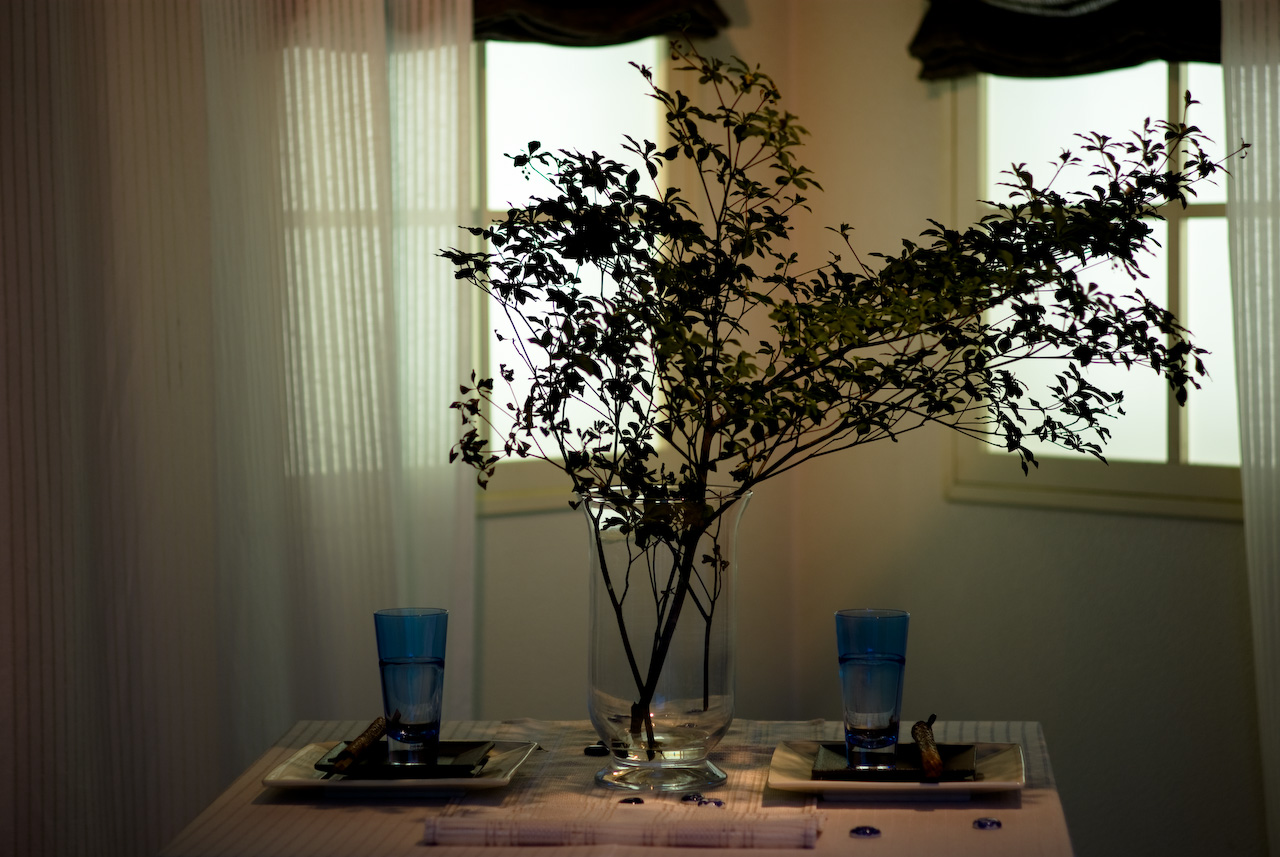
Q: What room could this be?
A: It is a dining room.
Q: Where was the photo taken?
A: It was taken at the dining room.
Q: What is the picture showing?
A: It is showing a dining room.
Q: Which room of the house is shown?
A: It is a dining room.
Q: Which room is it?
A: It is a dining room.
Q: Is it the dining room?
A: Yes, it is the dining room.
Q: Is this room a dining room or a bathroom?
A: It is a dining room.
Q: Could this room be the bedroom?
A: No, it is the dining room.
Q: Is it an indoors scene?
A: Yes, it is indoors.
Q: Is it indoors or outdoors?
A: It is indoors.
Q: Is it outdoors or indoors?
A: It is indoors.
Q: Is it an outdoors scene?
A: No, it is indoors.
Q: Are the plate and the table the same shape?
A: Yes, both the plate and the table are square.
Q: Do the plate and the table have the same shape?
A: Yes, both the plate and the table are square.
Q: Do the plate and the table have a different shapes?
A: No, both the plate and the table are square.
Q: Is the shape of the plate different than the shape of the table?
A: No, both the plate and the table are square.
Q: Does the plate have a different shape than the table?
A: No, both the plate and the table are square.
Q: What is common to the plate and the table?
A: The shape, both the plate and the table are square.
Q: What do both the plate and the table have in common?
A: The shape, both the plate and the table are square.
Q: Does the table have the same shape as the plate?
A: Yes, both the table and the plate are square.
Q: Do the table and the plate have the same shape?
A: Yes, both the table and the plate are square.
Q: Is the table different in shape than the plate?
A: No, both the table and the plate are square.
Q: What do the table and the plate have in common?
A: The shape, both the table and the plate are square.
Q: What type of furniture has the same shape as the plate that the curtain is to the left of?
A: The table is the same shape as the plate.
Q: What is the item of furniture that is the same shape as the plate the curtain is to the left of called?
A: The piece of furniture is a table.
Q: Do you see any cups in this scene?
A: Yes, there is a cup.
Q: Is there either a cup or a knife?
A: Yes, there is a cup.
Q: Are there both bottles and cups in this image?
A: No, there is a cup but no bottles.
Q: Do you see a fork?
A: No, there are no forks.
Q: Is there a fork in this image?
A: No, there are no forks.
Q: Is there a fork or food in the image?
A: No, there are no forks or food.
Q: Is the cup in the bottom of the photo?
A: Yes, the cup is in the bottom of the image.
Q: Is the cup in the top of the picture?
A: No, the cup is in the bottom of the image.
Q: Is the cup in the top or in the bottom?
A: The cup is in the bottom of the image.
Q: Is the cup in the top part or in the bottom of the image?
A: The cup is in the bottom of the image.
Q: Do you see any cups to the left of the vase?
A: Yes, there is a cup to the left of the vase.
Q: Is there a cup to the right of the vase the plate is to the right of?
A: No, the cup is to the left of the vase.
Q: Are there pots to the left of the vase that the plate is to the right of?
A: No, there is a cup to the left of the vase.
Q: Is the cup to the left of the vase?
A: Yes, the cup is to the left of the vase.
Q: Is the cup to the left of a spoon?
A: No, the cup is to the left of the vase.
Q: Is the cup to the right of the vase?
A: No, the cup is to the left of the vase.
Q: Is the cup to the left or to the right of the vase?
A: The cup is to the left of the vase.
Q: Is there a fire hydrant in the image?
A: No, there are no fire hydrants.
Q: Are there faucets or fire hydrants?
A: No, there are no fire hydrants or faucets.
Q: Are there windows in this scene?
A: Yes, there is a window.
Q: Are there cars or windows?
A: Yes, there is a window.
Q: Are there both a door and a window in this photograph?
A: No, there is a window but no doors.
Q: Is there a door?
A: No, there are no doors.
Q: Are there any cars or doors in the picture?
A: No, there are no doors or cars.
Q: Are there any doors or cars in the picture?
A: No, there are no doors or cars.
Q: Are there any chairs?
A: No, there are no chairs.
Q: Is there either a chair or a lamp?
A: No, there are no chairs or lamps.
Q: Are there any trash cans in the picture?
A: No, there are no trash cans.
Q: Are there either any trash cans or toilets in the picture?
A: No, there are no trash cans or toilets.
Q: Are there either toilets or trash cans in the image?
A: No, there are no trash cans or toilets.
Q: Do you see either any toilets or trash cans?
A: No, there are no trash cans or toilets.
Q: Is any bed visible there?
A: No, there are no beds.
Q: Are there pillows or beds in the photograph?
A: No, there are no beds or pillows.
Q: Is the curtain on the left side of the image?
A: Yes, the curtain is on the left of the image.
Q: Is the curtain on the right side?
A: No, the curtain is on the left of the image.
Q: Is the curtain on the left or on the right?
A: The curtain is on the left of the image.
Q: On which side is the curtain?
A: The curtain is on the left of the image.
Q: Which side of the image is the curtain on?
A: The curtain is on the left of the image.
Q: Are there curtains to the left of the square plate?
A: Yes, there is a curtain to the left of the plate.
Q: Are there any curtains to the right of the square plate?
A: No, the curtain is to the left of the plate.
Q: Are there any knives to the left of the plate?
A: No, there is a curtain to the left of the plate.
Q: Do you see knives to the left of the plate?
A: No, there is a curtain to the left of the plate.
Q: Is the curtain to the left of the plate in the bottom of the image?
A: Yes, the curtain is to the left of the plate.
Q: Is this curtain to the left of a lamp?
A: No, the curtain is to the left of the plate.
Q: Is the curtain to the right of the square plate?
A: No, the curtain is to the left of the plate.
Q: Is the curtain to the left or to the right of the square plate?
A: The curtain is to the left of the plate.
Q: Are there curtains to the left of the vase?
A: Yes, there is a curtain to the left of the vase.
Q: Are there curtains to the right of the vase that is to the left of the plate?
A: No, the curtain is to the left of the vase.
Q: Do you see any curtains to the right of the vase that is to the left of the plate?
A: No, the curtain is to the left of the vase.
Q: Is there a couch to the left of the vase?
A: No, there is a curtain to the left of the vase.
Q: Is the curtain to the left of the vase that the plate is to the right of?
A: Yes, the curtain is to the left of the vase.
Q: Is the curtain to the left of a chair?
A: No, the curtain is to the left of the vase.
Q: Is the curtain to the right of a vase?
A: No, the curtain is to the left of a vase.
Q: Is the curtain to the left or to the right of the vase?
A: The curtain is to the left of the vase.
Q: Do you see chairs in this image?
A: No, there are no chairs.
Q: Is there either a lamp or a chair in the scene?
A: No, there are no chairs or lamps.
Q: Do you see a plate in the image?
A: Yes, there is a plate.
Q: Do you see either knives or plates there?
A: Yes, there is a plate.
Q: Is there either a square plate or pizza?
A: Yes, there is a square plate.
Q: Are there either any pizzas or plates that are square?
A: Yes, the plate is square.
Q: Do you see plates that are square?
A: Yes, there is a square plate.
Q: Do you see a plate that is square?
A: Yes, there is a plate that is square.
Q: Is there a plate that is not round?
A: Yes, there is a square plate.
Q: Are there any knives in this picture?
A: No, there are no knives.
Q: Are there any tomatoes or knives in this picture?
A: No, there are no knives or tomatoes.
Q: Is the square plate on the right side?
A: Yes, the plate is on the right of the image.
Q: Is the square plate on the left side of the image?
A: No, the plate is on the right of the image.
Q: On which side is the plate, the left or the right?
A: The plate is on the right of the image.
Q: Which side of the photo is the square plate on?
A: The plate is on the right of the image.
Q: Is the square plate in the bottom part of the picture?
A: Yes, the plate is in the bottom of the image.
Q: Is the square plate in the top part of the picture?
A: No, the plate is in the bottom of the image.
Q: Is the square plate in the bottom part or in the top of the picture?
A: The plate is in the bottom of the image.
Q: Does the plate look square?
A: Yes, the plate is square.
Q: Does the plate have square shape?
A: Yes, the plate is square.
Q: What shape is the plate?
A: The plate is square.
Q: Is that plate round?
A: No, the plate is square.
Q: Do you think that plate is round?
A: No, the plate is square.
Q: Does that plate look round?
A: No, the plate is square.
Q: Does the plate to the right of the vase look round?
A: No, the plate is square.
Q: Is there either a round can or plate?
A: No, there is a plate but it is square.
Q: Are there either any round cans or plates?
A: No, there is a plate but it is square.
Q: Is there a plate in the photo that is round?
A: No, there is a plate but it is square.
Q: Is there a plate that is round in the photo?
A: No, there is a plate but it is square.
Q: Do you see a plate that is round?
A: No, there is a plate but it is square.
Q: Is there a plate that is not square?
A: No, there is a plate but it is square.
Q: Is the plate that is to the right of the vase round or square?
A: The plate is square.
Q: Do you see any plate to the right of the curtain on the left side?
A: Yes, there is a plate to the right of the curtain.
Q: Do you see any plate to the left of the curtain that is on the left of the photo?
A: No, the plate is to the right of the curtain.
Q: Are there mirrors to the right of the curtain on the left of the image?
A: No, there is a plate to the right of the curtain.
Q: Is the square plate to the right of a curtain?
A: Yes, the plate is to the right of a curtain.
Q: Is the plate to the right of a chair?
A: No, the plate is to the right of a curtain.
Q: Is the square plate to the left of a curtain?
A: No, the plate is to the right of a curtain.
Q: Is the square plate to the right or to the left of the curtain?
A: The plate is to the right of the curtain.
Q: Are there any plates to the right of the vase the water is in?
A: Yes, there is a plate to the right of the vase.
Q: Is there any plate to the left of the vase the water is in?
A: No, the plate is to the right of the vase.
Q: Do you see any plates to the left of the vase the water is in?
A: No, the plate is to the right of the vase.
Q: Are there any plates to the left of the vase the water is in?
A: No, the plate is to the right of the vase.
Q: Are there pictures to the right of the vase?
A: No, there is a plate to the right of the vase.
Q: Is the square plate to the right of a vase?
A: Yes, the plate is to the right of a vase.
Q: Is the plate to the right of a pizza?
A: No, the plate is to the right of a vase.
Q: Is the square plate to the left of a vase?
A: No, the plate is to the right of a vase.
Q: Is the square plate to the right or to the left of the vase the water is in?
A: The plate is to the right of the vase.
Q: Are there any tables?
A: Yes, there is a table.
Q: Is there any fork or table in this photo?
A: Yes, there is a table.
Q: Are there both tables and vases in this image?
A: Yes, there are both a table and a vase.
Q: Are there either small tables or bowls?
A: Yes, there is a small table.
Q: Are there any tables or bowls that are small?
A: Yes, the table is small.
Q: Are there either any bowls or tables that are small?
A: Yes, the table is small.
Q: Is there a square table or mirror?
A: Yes, there is a square table.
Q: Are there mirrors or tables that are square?
A: Yes, the table is square.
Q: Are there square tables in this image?
A: Yes, there is a square table.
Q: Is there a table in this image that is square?
A: Yes, there is a table that is square.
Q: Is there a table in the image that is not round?
A: Yes, there is a square table.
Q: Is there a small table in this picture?
A: Yes, there is a small table.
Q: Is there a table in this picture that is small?
A: Yes, there is a table that is small.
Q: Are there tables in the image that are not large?
A: Yes, there is a small table.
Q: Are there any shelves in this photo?
A: No, there are no shelves.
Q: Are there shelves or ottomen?
A: No, there are no shelves or ottomen.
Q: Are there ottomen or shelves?
A: No, there are no shelves or ottomen.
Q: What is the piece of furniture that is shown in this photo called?
A: The piece of furniture is a table.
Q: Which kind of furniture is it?
A: The piece of furniture is a table.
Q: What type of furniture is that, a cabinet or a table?
A: This is a table.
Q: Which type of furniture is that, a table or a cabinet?
A: This is a table.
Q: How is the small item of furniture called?
A: The piece of furniture is a table.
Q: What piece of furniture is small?
A: The piece of furniture is a table.